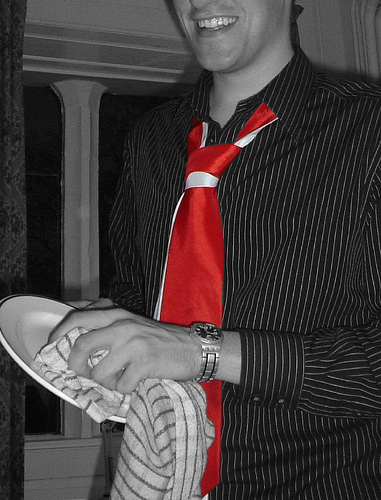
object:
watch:
[187, 322, 225, 384]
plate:
[0, 292, 127, 424]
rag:
[30, 325, 216, 498]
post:
[50, 79, 111, 299]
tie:
[152, 102, 278, 499]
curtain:
[1, 1, 24, 500]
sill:
[25, 433, 128, 477]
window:
[23, 26, 200, 301]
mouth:
[192, 14, 239, 36]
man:
[48, 1, 381, 500]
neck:
[208, 72, 234, 127]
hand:
[47, 296, 199, 393]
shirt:
[99, 42, 380, 498]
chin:
[197, 47, 245, 72]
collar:
[237, 46, 314, 141]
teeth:
[197, 18, 238, 29]